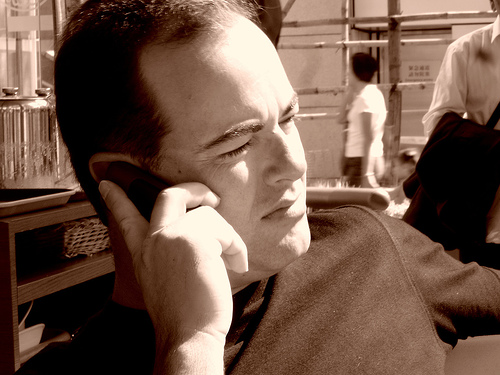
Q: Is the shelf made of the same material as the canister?
A: No, the shelf is made of wood and the canister is made of metal.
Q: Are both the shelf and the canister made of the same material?
A: No, the shelf is made of wood and the canister is made of metal.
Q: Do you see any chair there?
A: Yes, there is a chair.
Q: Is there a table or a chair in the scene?
A: Yes, there is a chair.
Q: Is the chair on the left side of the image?
A: Yes, the chair is on the left of the image.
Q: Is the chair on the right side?
A: No, the chair is on the left of the image.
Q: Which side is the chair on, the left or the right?
A: The chair is on the left of the image.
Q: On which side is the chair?
A: The chair is on the left of the image.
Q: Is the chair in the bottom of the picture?
A: Yes, the chair is in the bottom of the image.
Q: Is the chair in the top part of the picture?
A: No, the chair is in the bottom of the image.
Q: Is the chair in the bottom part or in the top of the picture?
A: The chair is in the bottom of the image.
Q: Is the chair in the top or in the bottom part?
A: The chair is in the bottom of the image.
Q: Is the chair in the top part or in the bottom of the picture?
A: The chair is in the bottom of the image.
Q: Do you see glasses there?
A: No, there are no glasses.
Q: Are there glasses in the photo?
A: No, there are no glasses.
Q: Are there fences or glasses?
A: No, there are no glasses or fences.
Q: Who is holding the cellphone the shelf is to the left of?
A: The man is holding the mobile phone.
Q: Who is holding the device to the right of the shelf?
A: The man is holding the mobile phone.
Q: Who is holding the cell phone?
A: The man is holding the mobile phone.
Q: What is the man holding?
A: The man is holding the cell phone.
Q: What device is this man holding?
A: The man is holding the cell phone.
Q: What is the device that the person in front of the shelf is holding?
A: The device is a cell phone.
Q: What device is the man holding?
A: The man is holding the cell phone.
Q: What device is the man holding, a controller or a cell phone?
A: The man is holding a cell phone.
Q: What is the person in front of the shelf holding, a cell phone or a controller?
A: The man is holding a cell phone.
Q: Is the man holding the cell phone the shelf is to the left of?
A: Yes, the man is holding the cellphone.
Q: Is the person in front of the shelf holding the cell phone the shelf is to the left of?
A: Yes, the man is holding the cellphone.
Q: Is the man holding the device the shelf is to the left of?
A: Yes, the man is holding the cellphone.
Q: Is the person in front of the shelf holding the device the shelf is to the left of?
A: Yes, the man is holding the cellphone.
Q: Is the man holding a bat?
A: No, the man is holding the cellphone.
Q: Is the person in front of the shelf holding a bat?
A: No, the man is holding the cellphone.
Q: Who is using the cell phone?
A: The man is using the cell phone.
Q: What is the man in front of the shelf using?
A: The man is using a cell phone.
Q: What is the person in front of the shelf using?
A: The man is using a cell phone.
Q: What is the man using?
A: The man is using a cell phone.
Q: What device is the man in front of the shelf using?
A: The man is using a mobile phone.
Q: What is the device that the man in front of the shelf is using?
A: The device is a cell phone.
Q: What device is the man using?
A: The man is using a mobile phone.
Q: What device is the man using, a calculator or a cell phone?
A: The man is using a cell phone.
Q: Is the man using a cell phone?
A: Yes, the man is using a cell phone.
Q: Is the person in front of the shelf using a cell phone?
A: Yes, the man is using a cell phone.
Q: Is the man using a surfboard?
A: No, the man is using a cell phone.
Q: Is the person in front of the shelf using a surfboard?
A: No, the man is using a cell phone.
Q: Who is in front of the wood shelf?
A: The man is in front of the shelf.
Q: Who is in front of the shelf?
A: The man is in front of the shelf.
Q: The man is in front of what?
A: The man is in front of the shelf.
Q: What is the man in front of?
A: The man is in front of the shelf.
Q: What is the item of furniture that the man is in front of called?
A: The piece of furniture is a shelf.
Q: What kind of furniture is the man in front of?
A: The man is in front of the shelf.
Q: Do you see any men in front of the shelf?
A: Yes, there is a man in front of the shelf.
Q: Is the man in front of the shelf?
A: Yes, the man is in front of the shelf.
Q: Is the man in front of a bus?
A: No, the man is in front of the shelf.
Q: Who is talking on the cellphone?
A: The man is talking on the cellphone.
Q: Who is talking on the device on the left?
A: The man is talking on the cellphone.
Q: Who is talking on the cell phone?
A: The man is talking on the cellphone.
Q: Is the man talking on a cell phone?
A: Yes, the man is talking on a cell phone.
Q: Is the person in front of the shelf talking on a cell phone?
A: Yes, the man is talking on a cell phone.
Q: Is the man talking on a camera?
A: No, the man is talking on a cell phone.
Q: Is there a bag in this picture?
A: Yes, there is a bag.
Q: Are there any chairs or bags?
A: Yes, there is a bag.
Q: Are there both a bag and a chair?
A: Yes, there are both a bag and a chair.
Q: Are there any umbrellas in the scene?
A: No, there are no umbrellas.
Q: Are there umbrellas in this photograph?
A: No, there are no umbrellas.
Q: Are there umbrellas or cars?
A: No, there are no umbrellas or cars.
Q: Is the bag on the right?
A: Yes, the bag is on the right of the image.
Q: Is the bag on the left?
A: No, the bag is on the right of the image.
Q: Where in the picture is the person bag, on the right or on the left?
A: The bag is on the right of the image.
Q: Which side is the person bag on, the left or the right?
A: The bag is on the right of the image.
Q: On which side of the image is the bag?
A: The bag is on the right of the image.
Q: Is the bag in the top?
A: Yes, the bag is in the top of the image.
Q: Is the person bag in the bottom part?
A: No, the bag is in the top of the image.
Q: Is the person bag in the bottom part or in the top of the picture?
A: The bag is in the top of the image.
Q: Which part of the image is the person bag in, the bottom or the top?
A: The bag is in the top of the image.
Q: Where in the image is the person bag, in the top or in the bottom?
A: The bag is in the top of the image.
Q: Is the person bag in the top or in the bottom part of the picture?
A: The bag is in the top of the image.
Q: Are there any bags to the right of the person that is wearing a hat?
A: Yes, there is a bag to the right of the person.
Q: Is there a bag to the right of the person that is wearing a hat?
A: Yes, there is a bag to the right of the person.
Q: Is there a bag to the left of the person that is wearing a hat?
A: No, the bag is to the right of the person.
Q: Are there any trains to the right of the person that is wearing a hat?
A: No, there is a bag to the right of the person.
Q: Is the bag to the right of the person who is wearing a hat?
A: Yes, the bag is to the right of the person.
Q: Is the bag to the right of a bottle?
A: No, the bag is to the right of the person.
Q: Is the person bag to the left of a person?
A: No, the bag is to the right of a person.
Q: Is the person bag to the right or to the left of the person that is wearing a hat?
A: The bag is to the right of the person.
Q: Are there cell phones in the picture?
A: Yes, there is a cell phone.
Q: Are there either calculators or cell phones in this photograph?
A: Yes, there is a cell phone.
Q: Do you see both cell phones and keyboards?
A: No, there is a cell phone but no keyboards.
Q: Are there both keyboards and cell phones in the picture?
A: No, there is a cell phone but no keyboards.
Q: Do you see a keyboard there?
A: No, there are no keyboards.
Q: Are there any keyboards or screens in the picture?
A: No, there are no keyboards or screens.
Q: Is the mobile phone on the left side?
A: Yes, the mobile phone is on the left of the image.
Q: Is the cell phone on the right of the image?
A: No, the cell phone is on the left of the image.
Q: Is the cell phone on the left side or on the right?
A: The cell phone is on the left of the image.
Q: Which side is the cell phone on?
A: The cell phone is on the left of the image.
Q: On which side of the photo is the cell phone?
A: The cell phone is on the left of the image.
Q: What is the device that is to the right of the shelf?
A: The device is a cell phone.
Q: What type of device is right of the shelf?
A: The device is a cell phone.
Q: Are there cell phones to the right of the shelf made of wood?
A: Yes, there is a cell phone to the right of the shelf.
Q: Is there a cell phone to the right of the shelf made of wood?
A: Yes, there is a cell phone to the right of the shelf.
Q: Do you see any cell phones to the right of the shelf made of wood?
A: Yes, there is a cell phone to the right of the shelf.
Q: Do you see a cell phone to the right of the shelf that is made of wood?
A: Yes, there is a cell phone to the right of the shelf.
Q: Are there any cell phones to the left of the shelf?
A: No, the cell phone is to the right of the shelf.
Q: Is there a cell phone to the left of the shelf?
A: No, the cell phone is to the right of the shelf.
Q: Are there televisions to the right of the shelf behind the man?
A: No, there is a cell phone to the right of the shelf.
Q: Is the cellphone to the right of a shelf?
A: Yes, the cellphone is to the right of a shelf.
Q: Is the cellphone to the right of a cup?
A: No, the cellphone is to the right of a shelf.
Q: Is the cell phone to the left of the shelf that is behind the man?
A: No, the cell phone is to the right of the shelf.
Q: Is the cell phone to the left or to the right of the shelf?
A: The cell phone is to the right of the shelf.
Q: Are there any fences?
A: No, there are no fences.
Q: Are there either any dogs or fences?
A: No, there are no fences or dogs.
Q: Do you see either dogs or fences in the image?
A: No, there are no fences or dogs.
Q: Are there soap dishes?
A: No, there are no soap dishes.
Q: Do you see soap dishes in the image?
A: No, there are no soap dishes.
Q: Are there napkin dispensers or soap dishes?
A: No, there are no soap dishes or napkin dispensers.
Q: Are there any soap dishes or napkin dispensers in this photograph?
A: No, there are no soap dishes or napkin dispensers.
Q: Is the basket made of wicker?
A: Yes, the basket is made of wicker.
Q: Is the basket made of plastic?
A: No, the basket is made of wicker.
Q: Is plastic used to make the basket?
A: No, the basket is made of wicker.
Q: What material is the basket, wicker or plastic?
A: The basket is made of wicker.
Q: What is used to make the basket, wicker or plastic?
A: The basket is made of wicker.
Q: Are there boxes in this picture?
A: No, there are no boxes.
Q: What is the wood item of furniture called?
A: The piece of furniture is a shelf.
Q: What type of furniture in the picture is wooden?
A: The furniture is a shelf.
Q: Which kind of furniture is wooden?
A: The furniture is a shelf.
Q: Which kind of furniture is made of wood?
A: The furniture is a shelf.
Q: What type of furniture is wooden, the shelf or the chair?
A: The shelf is wooden.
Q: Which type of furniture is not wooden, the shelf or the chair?
A: The chair is not wooden.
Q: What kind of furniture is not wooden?
A: The furniture is a chair.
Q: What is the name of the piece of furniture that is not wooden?
A: The piece of furniture is a chair.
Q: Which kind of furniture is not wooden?
A: The furniture is a chair.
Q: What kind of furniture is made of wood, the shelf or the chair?
A: The shelf is made of wood.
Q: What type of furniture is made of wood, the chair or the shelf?
A: The shelf is made of wood.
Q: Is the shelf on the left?
A: Yes, the shelf is on the left of the image.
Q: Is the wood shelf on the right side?
A: No, the shelf is on the left of the image.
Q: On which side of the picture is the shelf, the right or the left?
A: The shelf is on the left of the image.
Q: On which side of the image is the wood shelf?
A: The shelf is on the left of the image.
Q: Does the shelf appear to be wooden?
A: Yes, the shelf is wooden.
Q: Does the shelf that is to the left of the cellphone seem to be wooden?
A: Yes, the shelf is wooden.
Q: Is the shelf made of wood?
A: Yes, the shelf is made of wood.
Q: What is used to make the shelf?
A: The shelf is made of wood.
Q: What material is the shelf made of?
A: The shelf is made of wood.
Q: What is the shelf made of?
A: The shelf is made of wood.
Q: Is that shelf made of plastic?
A: No, the shelf is made of wood.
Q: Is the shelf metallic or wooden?
A: The shelf is wooden.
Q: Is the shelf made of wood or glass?
A: The shelf is made of wood.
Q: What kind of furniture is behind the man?
A: The piece of furniture is a shelf.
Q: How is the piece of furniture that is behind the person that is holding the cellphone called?
A: The piece of furniture is a shelf.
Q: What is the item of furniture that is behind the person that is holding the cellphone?
A: The piece of furniture is a shelf.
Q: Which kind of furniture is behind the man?
A: The piece of furniture is a shelf.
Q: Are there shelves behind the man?
A: Yes, there is a shelf behind the man.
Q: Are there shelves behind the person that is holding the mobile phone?
A: Yes, there is a shelf behind the man.